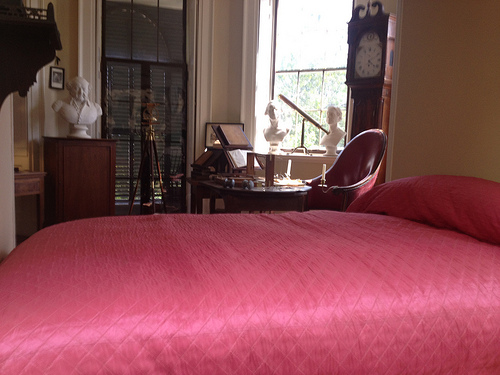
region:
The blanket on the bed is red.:
[105, 244, 260, 303]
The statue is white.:
[67, 76, 102, 140]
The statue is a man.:
[66, 78, 102, 138]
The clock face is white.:
[357, 33, 380, 78]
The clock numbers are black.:
[354, 38, 382, 78]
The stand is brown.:
[67, 140, 104, 205]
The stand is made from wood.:
[60, 148, 109, 199]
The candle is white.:
[320, 158, 329, 192]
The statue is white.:
[321, 105, 343, 156]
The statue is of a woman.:
[322, 105, 343, 151]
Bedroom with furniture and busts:
[1, 6, 476, 368]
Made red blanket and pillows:
[1, 158, 498, 363]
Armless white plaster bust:
[49, 78, 105, 137]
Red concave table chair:
[308, 129, 395, 206]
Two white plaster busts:
[264, 94, 341, 158]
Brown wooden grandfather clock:
[334, 7, 391, 133]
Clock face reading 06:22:
[353, 43, 383, 81]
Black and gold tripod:
[132, 127, 163, 214]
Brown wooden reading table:
[179, 165, 312, 210]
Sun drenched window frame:
[261, 13, 352, 150]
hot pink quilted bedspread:
[2, 172, 499, 373]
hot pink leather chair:
[300, 125, 387, 213]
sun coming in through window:
[271, 0, 346, 162]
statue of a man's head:
[316, 105, 347, 156]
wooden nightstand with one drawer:
[13, 168, 47, 234]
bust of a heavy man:
[47, 73, 105, 142]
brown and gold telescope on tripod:
[129, 99, 169, 212]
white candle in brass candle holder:
[315, 160, 329, 192]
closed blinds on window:
[105, 10, 186, 207]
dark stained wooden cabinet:
[40, 131, 119, 222]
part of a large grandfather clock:
[347, 3, 392, 136]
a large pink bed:
[2, 170, 499, 374]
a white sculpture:
[50, 73, 107, 139]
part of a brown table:
[190, 170, 302, 217]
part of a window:
[270, 0, 347, 142]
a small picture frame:
[49, 62, 69, 91]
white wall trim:
[190, 0, 215, 142]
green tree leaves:
[295, 65, 319, 107]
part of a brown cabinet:
[41, 126, 121, 212]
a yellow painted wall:
[387, 3, 498, 177]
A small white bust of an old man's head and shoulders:
[48, 68, 106, 138]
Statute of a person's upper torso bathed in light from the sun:
[254, 100, 294, 145]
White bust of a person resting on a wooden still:
[318, 100, 347, 155]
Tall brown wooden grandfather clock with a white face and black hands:
[338, 9, 387, 136]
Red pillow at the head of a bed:
[353, 165, 498, 253]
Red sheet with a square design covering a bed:
[26, 219, 479, 361]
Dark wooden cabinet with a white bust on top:
[45, 122, 123, 227]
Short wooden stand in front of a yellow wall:
[13, 155, 46, 228]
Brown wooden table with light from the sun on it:
[202, 165, 322, 204]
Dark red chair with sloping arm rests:
[315, 126, 378, 203]